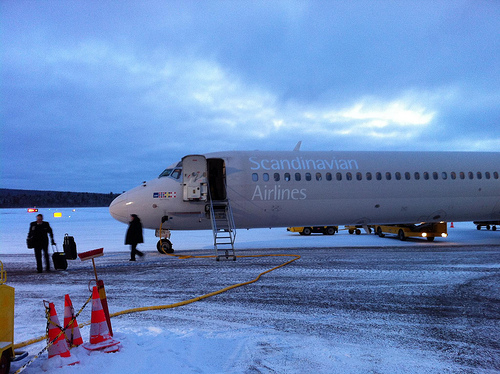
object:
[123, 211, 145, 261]
woman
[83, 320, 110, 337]
small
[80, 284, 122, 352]
cone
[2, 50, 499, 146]
thick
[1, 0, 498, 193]
sky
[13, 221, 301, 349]
cord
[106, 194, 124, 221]
nose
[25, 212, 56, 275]
man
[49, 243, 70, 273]
suitcase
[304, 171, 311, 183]
window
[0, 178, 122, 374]
left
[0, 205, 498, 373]
airport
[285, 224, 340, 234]
yellow trucks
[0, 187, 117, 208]
vegetation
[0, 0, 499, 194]
clouds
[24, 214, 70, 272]
travelling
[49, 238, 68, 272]
pulled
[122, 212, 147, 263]
walking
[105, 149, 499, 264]
plane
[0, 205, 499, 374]
ground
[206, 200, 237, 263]
ladder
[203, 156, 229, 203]
door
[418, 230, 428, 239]
lights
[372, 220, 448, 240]
truck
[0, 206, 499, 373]
runway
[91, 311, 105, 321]
yellow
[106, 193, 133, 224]
nose cone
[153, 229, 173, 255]
landing gear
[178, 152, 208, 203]
passenger door